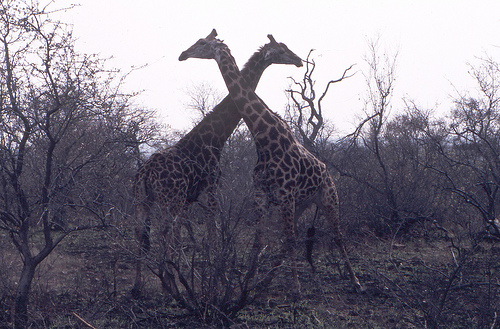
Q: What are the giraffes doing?
A: Crossing necks.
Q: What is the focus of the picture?
A: Giraffes.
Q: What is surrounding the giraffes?
A: Trees.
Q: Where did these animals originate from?
A: Africa.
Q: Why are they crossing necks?
A: Showing affection.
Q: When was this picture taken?
A: Daytime.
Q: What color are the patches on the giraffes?
A: Brown.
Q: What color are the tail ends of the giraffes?
A: Black.